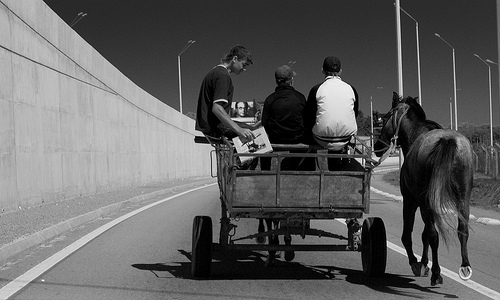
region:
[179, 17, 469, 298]
people riding in a wagon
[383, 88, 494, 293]
a horse trotting next to the wagon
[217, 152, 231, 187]
a rope on the wagon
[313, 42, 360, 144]
a man wearing a baseball cap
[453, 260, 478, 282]
metal horse shoe on a hoof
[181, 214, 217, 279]
black rubber wheel on the wagon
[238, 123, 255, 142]
a hand holding a magazine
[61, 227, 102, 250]
white lines on street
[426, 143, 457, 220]
long silky horse tail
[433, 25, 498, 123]
street light over the street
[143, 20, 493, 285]
People are in a horse drawn vehicle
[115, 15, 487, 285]
People are moving down a road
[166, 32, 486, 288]
A horse is walking down a road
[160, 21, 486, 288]
A horse is walking beside a vehicle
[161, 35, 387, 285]
Three people are in a vehicle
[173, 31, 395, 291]
Three people are on a road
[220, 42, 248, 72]
The head of a person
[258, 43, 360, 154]
Two people are wearing hats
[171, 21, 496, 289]
Three people are enjoying their evening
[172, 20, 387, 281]
Three friends are riding together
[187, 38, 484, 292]
A cart and horse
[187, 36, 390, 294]
Three people riding in a cart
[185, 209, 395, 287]
The wheels of a cart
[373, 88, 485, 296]
A horse walking on a road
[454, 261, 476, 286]
A shoe on a horse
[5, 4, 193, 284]
A curving wall beside a road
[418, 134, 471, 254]
The tail of a horse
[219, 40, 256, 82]
The head of a man looking down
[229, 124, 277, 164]
A hand holding a magazine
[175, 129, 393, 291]
The back of a horse cart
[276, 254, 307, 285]
part of a shade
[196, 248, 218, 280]
part of a wheel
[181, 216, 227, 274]
part of a wheel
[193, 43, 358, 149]
people sitting in a trailer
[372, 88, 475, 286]
a horse walking on the road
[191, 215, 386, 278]
the wheels under the trailer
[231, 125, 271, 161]
the paper in the boy's hand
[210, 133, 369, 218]
the back of a trailer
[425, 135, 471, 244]
the tail on the back of the horse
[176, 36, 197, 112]
a street light in the distance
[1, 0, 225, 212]
a concrete wall next to the road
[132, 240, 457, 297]
the shadow on the ground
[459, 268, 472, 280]
the horse's shoe